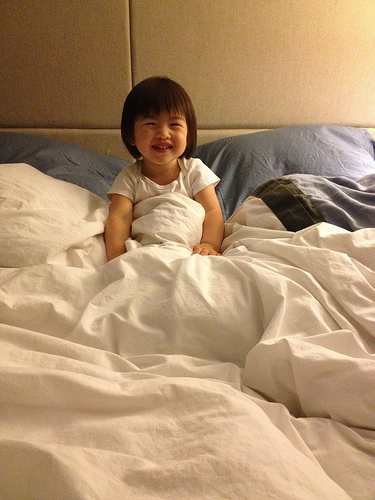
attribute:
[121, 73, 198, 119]
hair — dark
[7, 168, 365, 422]
covers — white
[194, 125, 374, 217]
pillow — blue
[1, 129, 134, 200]
pillow — blue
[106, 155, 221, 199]
shirt — white